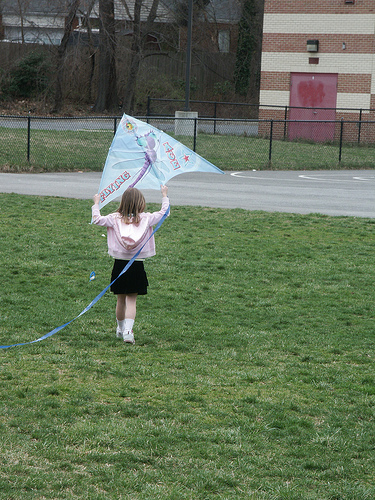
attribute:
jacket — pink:
[90, 197, 169, 261]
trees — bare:
[11, 5, 278, 120]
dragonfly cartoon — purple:
[129, 129, 158, 187]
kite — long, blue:
[88, 110, 225, 224]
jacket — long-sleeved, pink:
[87, 190, 177, 263]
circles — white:
[354, 176, 373, 180]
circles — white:
[299, 173, 370, 182]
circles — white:
[230, 170, 370, 182]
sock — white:
[125, 318, 133, 330]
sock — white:
[115, 317, 125, 330]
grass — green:
[172, 210, 372, 497]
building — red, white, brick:
[259, 0, 374, 147]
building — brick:
[334, 35, 361, 68]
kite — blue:
[92, 109, 218, 217]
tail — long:
[9, 220, 171, 352]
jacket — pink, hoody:
[87, 195, 173, 263]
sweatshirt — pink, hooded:
[93, 206, 154, 263]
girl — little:
[88, 184, 173, 343]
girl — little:
[59, 162, 203, 332]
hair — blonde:
[103, 182, 145, 232]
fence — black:
[194, 122, 372, 167]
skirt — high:
[106, 258, 148, 294]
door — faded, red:
[281, 62, 349, 130]